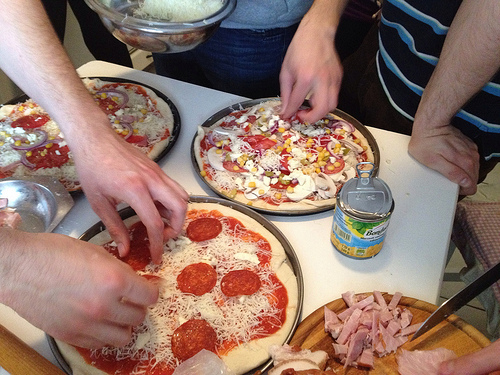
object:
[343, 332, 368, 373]
ham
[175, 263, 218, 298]
pepperoni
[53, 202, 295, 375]
pizza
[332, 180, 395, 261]
can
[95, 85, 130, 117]
onion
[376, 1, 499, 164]
shirt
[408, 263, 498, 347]
knife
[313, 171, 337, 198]
mushroom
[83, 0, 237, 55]
bowl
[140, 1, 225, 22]
cheese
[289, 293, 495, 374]
plate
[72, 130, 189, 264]
hand